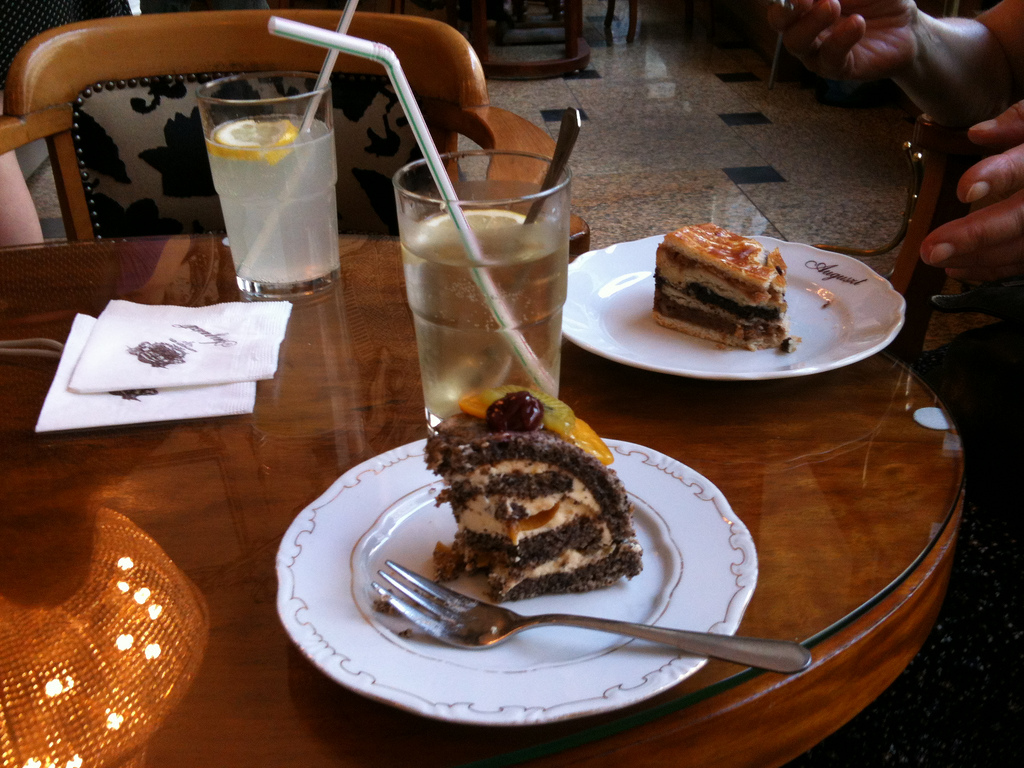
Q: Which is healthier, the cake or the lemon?
A: The lemon is healthier than the cake.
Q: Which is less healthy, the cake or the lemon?
A: The cake is less healthy than the lemon.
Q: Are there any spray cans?
A: No, there are no spray cans.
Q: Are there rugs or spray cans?
A: No, there are no spray cans or rugs.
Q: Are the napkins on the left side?
A: Yes, the napkins are on the left of the image.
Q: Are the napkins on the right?
A: No, the napkins are on the left of the image.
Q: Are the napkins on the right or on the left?
A: The napkins are on the left of the image.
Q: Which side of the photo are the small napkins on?
A: The napkins are on the left of the image.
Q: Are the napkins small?
A: Yes, the napkins are small.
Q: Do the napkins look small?
A: Yes, the napkins are small.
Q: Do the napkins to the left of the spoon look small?
A: Yes, the napkins are small.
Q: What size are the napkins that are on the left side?
A: The napkins are small.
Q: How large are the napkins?
A: The napkins are small.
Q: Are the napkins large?
A: No, the napkins are small.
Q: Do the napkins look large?
A: No, the napkins are small.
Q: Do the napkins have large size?
A: No, the napkins are small.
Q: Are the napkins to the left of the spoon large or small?
A: The napkins are small.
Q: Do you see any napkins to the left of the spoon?
A: Yes, there are napkins to the left of the spoon.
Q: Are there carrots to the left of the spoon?
A: No, there are napkins to the left of the spoon.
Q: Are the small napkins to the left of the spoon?
A: Yes, the napkins are to the left of the spoon.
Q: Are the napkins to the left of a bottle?
A: No, the napkins are to the left of the spoon.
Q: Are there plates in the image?
A: Yes, there is a plate.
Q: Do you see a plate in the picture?
A: Yes, there is a plate.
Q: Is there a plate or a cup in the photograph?
A: Yes, there is a plate.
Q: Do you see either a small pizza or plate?
A: Yes, there is a small plate.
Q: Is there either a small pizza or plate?
A: Yes, there is a small plate.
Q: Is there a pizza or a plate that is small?
A: Yes, the plate is small.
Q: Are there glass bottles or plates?
A: Yes, there is a glass plate.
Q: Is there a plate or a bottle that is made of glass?
A: Yes, the plate is made of glass.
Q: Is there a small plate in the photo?
A: Yes, there is a small plate.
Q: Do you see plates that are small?
A: Yes, there is a plate that is small.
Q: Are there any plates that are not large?
A: Yes, there is a small plate.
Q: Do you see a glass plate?
A: Yes, there is a plate that is made of glass.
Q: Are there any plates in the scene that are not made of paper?
A: Yes, there is a plate that is made of glass.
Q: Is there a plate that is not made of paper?
A: Yes, there is a plate that is made of glass.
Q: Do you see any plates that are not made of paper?
A: Yes, there is a plate that is made of glass.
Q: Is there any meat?
A: No, there is no meat.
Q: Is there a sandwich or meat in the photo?
A: No, there are no meat or sandwiches.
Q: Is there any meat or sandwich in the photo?
A: No, there are no meat or sandwiches.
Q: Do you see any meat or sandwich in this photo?
A: No, there are no meat or sandwiches.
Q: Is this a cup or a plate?
A: This is a plate.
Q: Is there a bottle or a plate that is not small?
A: No, there is a plate but it is small.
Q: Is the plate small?
A: Yes, the plate is small.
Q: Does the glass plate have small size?
A: Yes, the plate is small.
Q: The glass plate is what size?
A: The plate is small.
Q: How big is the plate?
A: The plate is small.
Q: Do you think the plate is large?
A: No, the plate is small.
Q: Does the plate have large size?
A: No, the plate is small.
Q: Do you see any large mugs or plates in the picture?
A: No, there is a plate but it is small.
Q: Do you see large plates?
A: No, there is a plate but it is small.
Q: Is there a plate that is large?
A: No, there is a plate but it is small.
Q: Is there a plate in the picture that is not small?
A: No, there is a plate but it is small.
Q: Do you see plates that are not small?
A: No, there is a plate but it is small.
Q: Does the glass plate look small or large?
A: The plate is small.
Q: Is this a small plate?
A: Yes, this is a small plate.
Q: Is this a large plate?
A: No, this is a small plate.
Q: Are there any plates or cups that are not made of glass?
A: No, there is a plate but it is made of glass.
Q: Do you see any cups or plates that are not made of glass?
A: No, there is a plate but it is made of glass.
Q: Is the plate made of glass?
A: Yes, the plate is made of glass.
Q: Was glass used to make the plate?
A: Yes, the plate is made of glass.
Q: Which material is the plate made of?
A: The plate is made of glass.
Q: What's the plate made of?
A: The plate is made of glass.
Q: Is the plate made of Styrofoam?
A: No, the plate is made of glass.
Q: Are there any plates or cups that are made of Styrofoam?
A: No, there is a plate but it is made of glass.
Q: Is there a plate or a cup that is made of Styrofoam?
A: No, there is a plate but it is made of glass.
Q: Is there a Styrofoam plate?
A: No, there is a plate but it is made of glass.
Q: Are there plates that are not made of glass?
A: No, there is a plate but it is made of glass.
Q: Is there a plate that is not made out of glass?
A: No, there is a plate but it is made of glass.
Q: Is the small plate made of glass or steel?
A: The plate is made of glass.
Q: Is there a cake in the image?
A: Yes, there is a cake.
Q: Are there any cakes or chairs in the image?
A: Yes, there is a cake.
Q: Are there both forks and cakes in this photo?
A: Yes, there are both a cake and a fork.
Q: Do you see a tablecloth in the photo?
A: No, there are no tablecloths.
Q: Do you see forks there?
A: Yes, there is a fork.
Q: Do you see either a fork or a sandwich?
A: Yes, there is a fork.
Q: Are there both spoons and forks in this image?
A: Yes, there are both a fork and spoons.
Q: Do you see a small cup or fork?
A: Yes, there is a small fork.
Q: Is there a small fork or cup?
A: Yes, there is a small fork.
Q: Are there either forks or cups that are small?
A: Yes, the fork is small.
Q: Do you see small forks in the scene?
A: Yes, there is a small fork.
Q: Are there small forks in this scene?
A: Yes, there is a small fork.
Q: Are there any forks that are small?
A: Yes, there is a fork that is small.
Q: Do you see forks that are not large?
A: Yes, there is a small fork.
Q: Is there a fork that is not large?
A: Yes, there is a small fork.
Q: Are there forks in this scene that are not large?
A: Yes, there is a small fork.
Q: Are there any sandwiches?
A: No, there are no sandwiches.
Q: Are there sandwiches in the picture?
A: No, there are no sandwiches.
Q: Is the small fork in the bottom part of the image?
A: Yes, the fork is in the bottom of the image.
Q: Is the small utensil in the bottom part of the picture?
A: Yes, the fork is in the bottom of the image.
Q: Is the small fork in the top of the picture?
A: No, the fork is in the bottom of the image.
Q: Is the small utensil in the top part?
A: No, the fork is in the bottom of the image.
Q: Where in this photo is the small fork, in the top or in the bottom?
A: The fork is in the bottom of the image.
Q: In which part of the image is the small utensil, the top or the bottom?
A: The fork is in the bottom of the image.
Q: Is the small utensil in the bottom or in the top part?
A: The fork is in the bottom of the image.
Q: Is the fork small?
A: Yes, the fork is small.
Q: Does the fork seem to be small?
A: Yes, the fork is small.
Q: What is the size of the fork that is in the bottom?
A: The fork is small.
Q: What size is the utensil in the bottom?
A: The fork is small.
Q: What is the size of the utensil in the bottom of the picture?
A: The fork is small.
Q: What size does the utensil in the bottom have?
A: The fork has small size.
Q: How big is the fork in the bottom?
A: The fork is small.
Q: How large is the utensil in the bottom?
A: The fork is small.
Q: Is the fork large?
A: No, the fork is small.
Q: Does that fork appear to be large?
A: No, the fork is small.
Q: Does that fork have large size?
A: No, the fork is small.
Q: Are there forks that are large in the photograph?
A: No, there is a fork but it is small.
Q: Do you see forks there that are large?
A: No, there is a fork but it is small.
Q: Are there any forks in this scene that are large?
A: No, there is a fork but it is small.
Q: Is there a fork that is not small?
A: No, there is a fork but it is small.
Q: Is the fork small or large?
A: The fork is small.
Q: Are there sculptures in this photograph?
A: No, there are no sculptures.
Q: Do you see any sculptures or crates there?
A: No, there are no sculptures or crates.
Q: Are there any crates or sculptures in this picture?
A: No, there are no sculptures or crates.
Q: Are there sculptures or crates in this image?
A: No, there are no sculptures or crates.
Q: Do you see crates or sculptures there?
A: No, there are no sculptures or crates.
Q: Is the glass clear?
A: Yes, the glass is clear.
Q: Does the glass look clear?
A: Yes, the glass is clear.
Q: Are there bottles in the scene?
A: No, there are no bottles.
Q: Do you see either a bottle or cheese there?
A: No, there are no bottles or cheese.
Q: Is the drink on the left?
A: Yes, the drink is on the left of the image.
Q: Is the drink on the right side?
A: No, the drink is on the left of the image.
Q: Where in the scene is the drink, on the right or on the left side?
A: The drink is on the left of the image.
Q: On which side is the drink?
A: The drink is on the left of the image.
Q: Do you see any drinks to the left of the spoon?
A: Yes, there is a drink to the left of the spoon.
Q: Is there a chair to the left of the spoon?
A: No, there is a drink to the left of the spoon.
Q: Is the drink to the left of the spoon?
A: Yes, the drink is to the left of the spoon.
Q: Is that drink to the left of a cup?
A: No, the drink is to the left of the spoon.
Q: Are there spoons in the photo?
A: Yes, there is a spoon.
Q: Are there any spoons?
A: Yes, there is a spoon.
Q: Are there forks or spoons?
A: Yes, there is a spoon.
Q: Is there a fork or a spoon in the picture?
A: Yes, there is a spoon.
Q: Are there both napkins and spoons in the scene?
A: Yes, there are both a spoon and a napkin.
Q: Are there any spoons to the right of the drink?
A: Yes, there is a spoon to the right of the drink.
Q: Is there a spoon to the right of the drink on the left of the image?
A: Yes, there is a spoon to the right of the drink.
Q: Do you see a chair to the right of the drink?
A: No, there is a spoon to the right of the drink.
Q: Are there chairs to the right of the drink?
A: No, there is a spoon to the right of the drink.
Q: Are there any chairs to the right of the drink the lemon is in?
A: No, there is a spoon to the right of the drink.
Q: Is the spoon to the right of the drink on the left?
A: Yes, the spoon is to the right of the drink.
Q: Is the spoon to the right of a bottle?
A: No, the spoon is to the right of the drink.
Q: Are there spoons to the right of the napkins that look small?
A: Yes, there is a spoon to the right of the napkins.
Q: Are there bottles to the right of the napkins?
A: No, there is a spoon to the right of the napkins.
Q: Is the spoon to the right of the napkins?
A: Yes, the spoon is to the right of the napkins.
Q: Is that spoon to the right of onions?
A: No, the spoon is to the right of the napkins.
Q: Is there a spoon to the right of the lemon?
A: Yes, there is a spoon to the right of the lemon.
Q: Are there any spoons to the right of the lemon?
A: Yes, there is a spoon to the right of the lemon.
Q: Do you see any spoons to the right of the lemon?
A: Yes, there is a spoon to the right of the lemon.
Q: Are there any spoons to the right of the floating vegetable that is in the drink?
A: Yes, there is a spoon to the right of the lemon.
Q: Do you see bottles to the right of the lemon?
A: No, there is a spoon to the right of the lemon.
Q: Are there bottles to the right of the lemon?
A: No, there is a spoon to the right of the lemon.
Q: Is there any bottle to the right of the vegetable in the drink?
A: No, there is a spoon to the right of the lemon.